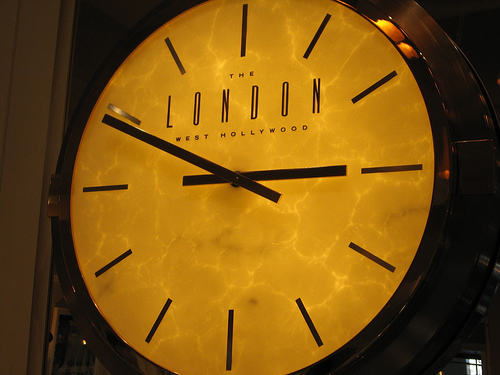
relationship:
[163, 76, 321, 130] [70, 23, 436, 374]
lettering on clock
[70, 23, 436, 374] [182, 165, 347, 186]
clock has hand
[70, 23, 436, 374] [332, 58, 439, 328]
clock has numbers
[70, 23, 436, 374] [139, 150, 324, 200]
clock has hand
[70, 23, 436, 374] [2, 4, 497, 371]
clock on building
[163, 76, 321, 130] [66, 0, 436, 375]
lettering printed on clock face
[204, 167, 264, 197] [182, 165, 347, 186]
bolt holding hand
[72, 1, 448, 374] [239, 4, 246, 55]
clock face has line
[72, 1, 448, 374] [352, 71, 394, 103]
clock face has line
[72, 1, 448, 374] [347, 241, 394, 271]
clock face has line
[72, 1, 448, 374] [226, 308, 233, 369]
clock face has line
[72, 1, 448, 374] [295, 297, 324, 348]
clock face has line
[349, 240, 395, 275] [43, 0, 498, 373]
tick mark on clock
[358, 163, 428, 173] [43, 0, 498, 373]
tick mark on clock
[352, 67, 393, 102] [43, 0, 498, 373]
tick mark on clock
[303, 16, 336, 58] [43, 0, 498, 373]
tick mark on clock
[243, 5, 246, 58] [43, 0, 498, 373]
tick mark on clock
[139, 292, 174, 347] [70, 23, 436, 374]
tick mark on clock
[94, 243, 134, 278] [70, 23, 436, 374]
tick mark on clock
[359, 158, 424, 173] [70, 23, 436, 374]
tick mark on clock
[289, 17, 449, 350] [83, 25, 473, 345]
reflection on clock